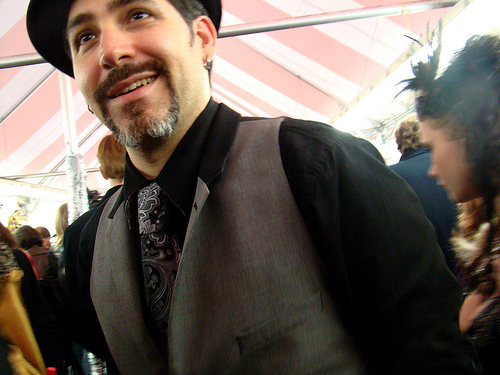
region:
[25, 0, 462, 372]
a man standing under a tent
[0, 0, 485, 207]
a large tent above the people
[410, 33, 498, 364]
a woman next to the man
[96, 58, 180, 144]
a goatee on the man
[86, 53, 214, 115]
earrings on the man's ears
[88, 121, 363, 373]
gray vest on the man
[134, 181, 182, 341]
tie on the man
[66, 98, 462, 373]
black shirt on the man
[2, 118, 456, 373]
crowd behind the man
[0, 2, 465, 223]
metal poles of the tent frame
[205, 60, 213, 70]
Earring in man's ear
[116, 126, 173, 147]
Gray and black beard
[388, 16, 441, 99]
Feathers on girl's hat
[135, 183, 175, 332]
Gray and black tie on man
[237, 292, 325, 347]
Pocket on man's gray vest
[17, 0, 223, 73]
Rim of black hat on man's head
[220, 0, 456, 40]
Silver metal pole support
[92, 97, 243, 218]
Man's black shirt collar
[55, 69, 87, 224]
Vertical metal pole support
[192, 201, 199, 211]
Button hole on man's vest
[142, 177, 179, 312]
The tie the man is wearing.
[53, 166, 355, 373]
The gray vest the man is wearing.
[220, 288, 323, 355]
The pocket on the man's vest.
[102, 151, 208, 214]
The collar of the black shirt the man is wearing.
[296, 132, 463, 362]
The right sleeve of the black shirt the man is wearing.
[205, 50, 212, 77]
The earring in the man's right ear.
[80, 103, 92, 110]
The left earring in the man's ear.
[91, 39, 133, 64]
The nose of the man.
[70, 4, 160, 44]
The eyes of the man.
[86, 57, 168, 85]
The moustache of the man.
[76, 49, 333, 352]
this is a man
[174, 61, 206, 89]
the man is light skinned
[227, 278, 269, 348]
this is a half coat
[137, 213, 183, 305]
this is a neck tie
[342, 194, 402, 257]
this is a shirt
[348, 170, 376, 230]
the shirt is black in color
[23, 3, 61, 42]
this is a hat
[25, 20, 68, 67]
the hat is black in color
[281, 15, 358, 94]
this is a tent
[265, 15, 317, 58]
this is the pole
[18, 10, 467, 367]
man wearing black shirt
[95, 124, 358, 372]
gray vest of the man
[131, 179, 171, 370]
black paisley print necktie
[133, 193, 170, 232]
knot of the necktie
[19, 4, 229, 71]
brim of black hat man is wearing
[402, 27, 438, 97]
feathers in woman's hair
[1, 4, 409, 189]
striped ceiling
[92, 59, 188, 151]
goatee of man wearing black shirt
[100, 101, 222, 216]
black collar of man in gray vest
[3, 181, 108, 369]
people on the left side